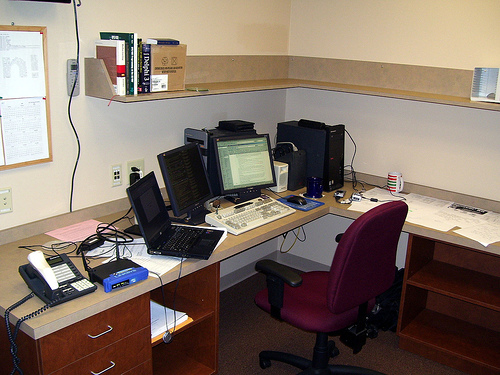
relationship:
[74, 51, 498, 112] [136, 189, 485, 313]
shelf above desk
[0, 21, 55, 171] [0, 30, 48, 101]
board with paper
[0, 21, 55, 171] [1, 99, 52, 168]
board with paper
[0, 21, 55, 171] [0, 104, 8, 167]
board with paper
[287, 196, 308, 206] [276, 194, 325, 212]
computer mouse on mousepad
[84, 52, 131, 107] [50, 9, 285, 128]
end of shelf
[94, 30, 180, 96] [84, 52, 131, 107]
books on end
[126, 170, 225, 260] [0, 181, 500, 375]
laptop on desk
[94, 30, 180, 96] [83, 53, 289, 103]
books on shelf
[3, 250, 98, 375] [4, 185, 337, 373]
telephone on desk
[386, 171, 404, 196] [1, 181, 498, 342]
cup on desk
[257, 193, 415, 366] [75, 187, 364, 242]
chair at desk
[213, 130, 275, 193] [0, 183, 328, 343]
computer monitor on desk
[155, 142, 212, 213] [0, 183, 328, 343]
computer monitor on desk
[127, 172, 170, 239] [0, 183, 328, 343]
computer monitor on desk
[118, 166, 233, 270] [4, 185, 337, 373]
laptop on desk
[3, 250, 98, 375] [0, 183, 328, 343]
telephone on desk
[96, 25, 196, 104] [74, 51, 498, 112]
books on shelf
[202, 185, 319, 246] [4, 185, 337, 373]
keyboard on desk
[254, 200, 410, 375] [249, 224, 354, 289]
chair has arms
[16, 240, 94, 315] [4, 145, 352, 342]
telephone on desk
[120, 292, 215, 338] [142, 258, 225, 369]
papers on shelf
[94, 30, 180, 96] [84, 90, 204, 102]
books on shelf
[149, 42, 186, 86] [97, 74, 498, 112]
cardboard box on shelf